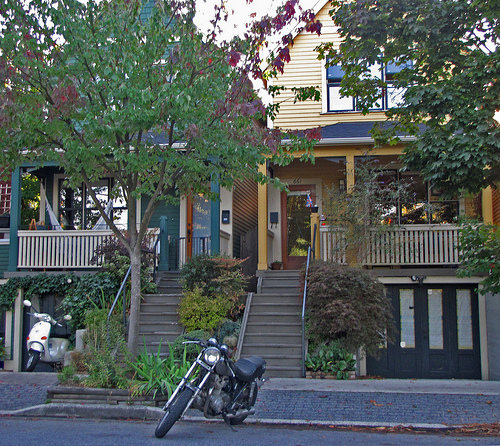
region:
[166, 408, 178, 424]
the tire is black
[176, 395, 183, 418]
the tire is black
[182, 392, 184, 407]
the tire is black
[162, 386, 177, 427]
the tire is black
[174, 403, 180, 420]
the tire is black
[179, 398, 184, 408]
the tire is black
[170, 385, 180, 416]
the tire is black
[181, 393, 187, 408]
the tire is black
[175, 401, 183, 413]
the tire is black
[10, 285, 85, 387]
this is a moped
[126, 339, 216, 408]
these are tall weeds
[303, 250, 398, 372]
this is a bush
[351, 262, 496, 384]
these are garage doors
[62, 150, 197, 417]
this is a tree trunk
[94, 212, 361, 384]
these are the stairs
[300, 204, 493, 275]
this is a fence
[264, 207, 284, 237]
this is the mailbox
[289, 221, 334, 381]
this is stair railing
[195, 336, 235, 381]
this is the motorcycle headlight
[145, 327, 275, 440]
a black motorcycle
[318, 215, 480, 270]
a beige wooden porch rail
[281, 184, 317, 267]
the door of a building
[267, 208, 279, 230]
a small black mailbox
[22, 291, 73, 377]
a white moped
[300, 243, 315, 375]
an iron porch rail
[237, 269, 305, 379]
a long porch staircase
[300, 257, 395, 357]
a small bush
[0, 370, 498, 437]
a brick sidewalk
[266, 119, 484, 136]
the roof of a home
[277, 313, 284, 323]
part of a stair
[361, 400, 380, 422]
edge of a road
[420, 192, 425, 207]
part of a window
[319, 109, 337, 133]
part of a house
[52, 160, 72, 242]
part of a balcony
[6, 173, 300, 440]
two two wheeled vehicles parked in front of houses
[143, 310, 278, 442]
motorcycle parked at curb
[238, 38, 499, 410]
yellow house with porch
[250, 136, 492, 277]
covered porch with white railing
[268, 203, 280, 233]
black rectangular mailbox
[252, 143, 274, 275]
yellow wooden porch post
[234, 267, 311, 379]
several steps leading up to house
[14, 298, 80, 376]
white moped with two mirrors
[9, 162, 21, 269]
green wooden porch post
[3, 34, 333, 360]
tree with leaves starting to turn red